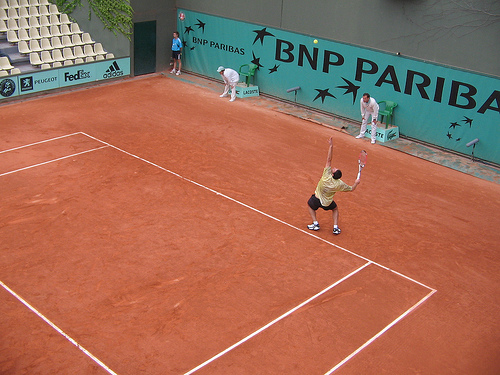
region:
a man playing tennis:
[149, 26, 453, 305]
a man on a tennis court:
[205, 78, 443, 294]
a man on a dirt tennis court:
[241, 91, 439, 290]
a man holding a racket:
[278, 118, 395, 248]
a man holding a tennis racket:
[261, 122, 414, 292]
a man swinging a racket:
[264, 107, 422, 267]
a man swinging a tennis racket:
[272, 94, 432, 312]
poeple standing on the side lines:
[165, 9, 415, 157]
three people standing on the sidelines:
[160, 12, 437, 187]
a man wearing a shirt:
[214, 73, 442, 327]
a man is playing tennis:
[142, 127, 455, 287]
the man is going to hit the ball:
[277, 5, 388, 259]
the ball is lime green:
[288, 9, 337, 96]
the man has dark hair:
[322, 159, 345, 189]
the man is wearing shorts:
[264, 187, 367, 262]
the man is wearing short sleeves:
[305, 160, 380, 225]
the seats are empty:
[23, 3, 125, 78]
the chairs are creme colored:
[7, 0, 108, 72]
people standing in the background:
[145, 26, 411, 151]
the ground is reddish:
[106, 137, 357, 344]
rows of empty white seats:
[5, 3, 113, 69]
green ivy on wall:
[67, 0, 134, 56]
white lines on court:
[0, 131, 438, 371]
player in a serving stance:
[303, 136, 370, 236]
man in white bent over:
[357, 94, 380, 146]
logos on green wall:
[0, 57, 132, 101]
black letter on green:
[282, 42, 497, 114]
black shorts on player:
[308, 193, 338, 212]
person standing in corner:
[169, 28, 184, 79]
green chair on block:
[370, 97, 400, 141]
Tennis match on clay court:
[11, 13, 483, 373]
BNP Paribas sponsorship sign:
[271, 20, 498, 120]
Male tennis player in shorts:
[293, 134, 380, 236]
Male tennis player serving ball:
[300, 134, 377, 192]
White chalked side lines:
[273, 256, 439, 358]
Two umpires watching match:
[210, 57, 412, 147]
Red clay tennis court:
[18, 182, 495, 369]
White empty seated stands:
[5, 23, 135, 67]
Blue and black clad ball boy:
[160, 29, 188, 80]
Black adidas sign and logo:
[101, 62, 126, 83]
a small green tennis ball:
[310, 36, 321, 44]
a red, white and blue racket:
[359, 144, 370, 168]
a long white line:
[81, 124, 441, 295]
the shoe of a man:
[332, 222, 345, 234]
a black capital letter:
[352, 55, 381, 87]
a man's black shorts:
[305, 187, 339, 212]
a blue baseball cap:
[213, 63, 225, 71]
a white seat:
[80, 28, 96, 45]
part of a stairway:
[0, 37, 32, 74]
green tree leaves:
[87, 0, 138, 36]